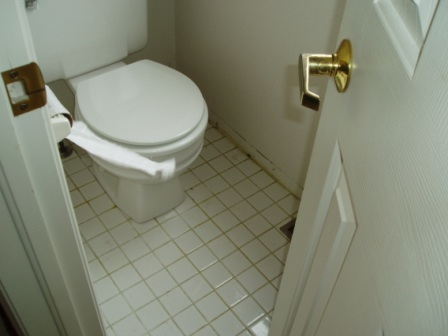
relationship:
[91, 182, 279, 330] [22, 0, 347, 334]
floor inside bathroom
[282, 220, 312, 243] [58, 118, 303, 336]
vent visible on floor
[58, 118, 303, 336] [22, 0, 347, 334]
floor inside bathroom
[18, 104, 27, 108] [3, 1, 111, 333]
screw on frame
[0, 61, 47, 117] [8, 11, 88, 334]
latch on wall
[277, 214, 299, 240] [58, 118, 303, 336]
heater on floor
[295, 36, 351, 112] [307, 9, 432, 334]
door handle on door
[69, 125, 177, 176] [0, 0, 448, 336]
toilet paper on bathroom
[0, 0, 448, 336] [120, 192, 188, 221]
bathroom has base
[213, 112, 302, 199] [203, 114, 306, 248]
baseboard on floor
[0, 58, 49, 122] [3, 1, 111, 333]
latch in frame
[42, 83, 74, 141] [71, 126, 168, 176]
roll has paper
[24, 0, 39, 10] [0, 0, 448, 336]
lever on bathroom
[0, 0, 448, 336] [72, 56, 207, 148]
bathroom has lid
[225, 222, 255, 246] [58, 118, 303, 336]
tile on floor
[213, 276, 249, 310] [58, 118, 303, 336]
tile on floor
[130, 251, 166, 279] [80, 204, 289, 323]
white tile on floor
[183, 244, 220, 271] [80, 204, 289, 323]
white tile on floor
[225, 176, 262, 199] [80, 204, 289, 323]
white tile on floor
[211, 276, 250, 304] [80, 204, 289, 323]
white tile on floor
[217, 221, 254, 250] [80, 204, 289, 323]
white tile on floor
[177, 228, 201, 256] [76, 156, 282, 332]
white tile on floor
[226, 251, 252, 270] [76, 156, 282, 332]
white tile on floor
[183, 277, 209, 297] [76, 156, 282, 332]
white tile on floor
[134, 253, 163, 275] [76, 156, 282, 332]
white tile on floor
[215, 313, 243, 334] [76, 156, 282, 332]
white tile on floor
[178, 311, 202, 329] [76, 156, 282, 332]
tile on floor